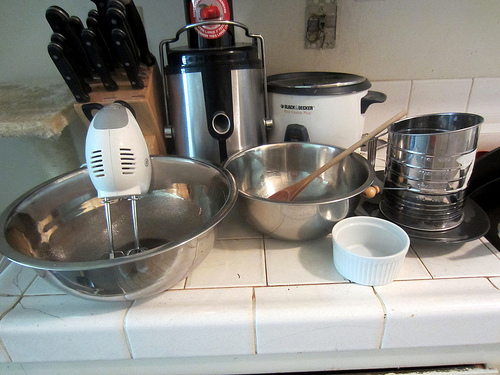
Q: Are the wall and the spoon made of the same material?
A: No, the wall is made of concrete and the spoon is made of wood.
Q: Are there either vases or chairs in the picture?
A: No, there are no chairs or vases.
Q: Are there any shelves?
A: No, there are no shelves.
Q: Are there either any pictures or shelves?
A: No, there are no shelves or pictures.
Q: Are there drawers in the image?
A: No, there are no drawers.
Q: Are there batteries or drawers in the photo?
A: No, there are no drawers or batteries.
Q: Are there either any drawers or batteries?
A: No, there are no drawers or batteries.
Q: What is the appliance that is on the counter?
A: The appliance is a cooker.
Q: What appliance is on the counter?
A: The appliance is a cooker.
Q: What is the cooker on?
A: The cooker is on the counter.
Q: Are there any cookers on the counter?
A: Yes, there is a cooker on the counter.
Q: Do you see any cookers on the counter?
A: Yes, there is a cooker on the counter.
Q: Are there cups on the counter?
A: No, there is a cooker on the counter.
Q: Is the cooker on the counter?
A: Yes, the cooker is on the counter.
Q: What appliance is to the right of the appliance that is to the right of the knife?
A: The appliance is a cooker.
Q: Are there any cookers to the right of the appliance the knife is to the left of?
A: Yes, there is a cooker to the right of the appliance.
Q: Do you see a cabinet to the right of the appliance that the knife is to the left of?
A: No, there is a cooker to the right of the appliance.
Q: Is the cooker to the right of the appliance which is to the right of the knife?
A: Yes, the cooker is to the right of the appliance.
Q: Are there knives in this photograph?
A: Yes, there is a knife.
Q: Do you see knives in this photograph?
A: Yes, there is a knife.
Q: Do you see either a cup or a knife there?
A: Yes, there is a knife.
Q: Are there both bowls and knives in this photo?
A: Yes, there are both a knife and a bowl.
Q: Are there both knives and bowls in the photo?
A: Yes, there are both a knife and a bowl.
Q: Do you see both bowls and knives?
A: Yes, there are both a knife and a bowl.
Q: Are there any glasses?
A: No, there are no glasses.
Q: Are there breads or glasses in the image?
A: No, there are no glasses or breads.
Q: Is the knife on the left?
A: Yes, the knife is on the left of the image.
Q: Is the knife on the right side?
A: No, the knife is on the left of the image.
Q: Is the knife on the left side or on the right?
A: The knife is on the left of the image.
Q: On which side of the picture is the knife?
A: The knife is on the left of the image.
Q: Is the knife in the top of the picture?
A: Yes, the knife is in the top of the image.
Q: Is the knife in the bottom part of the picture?
A: No, the knife is in the top of the image.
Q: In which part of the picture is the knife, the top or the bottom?
A: The knife is in the top of the image.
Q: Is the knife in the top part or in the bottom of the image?
A: The knife is in the top of the image.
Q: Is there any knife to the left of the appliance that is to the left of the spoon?
A: Yes, there is a knife to the left of the appliance.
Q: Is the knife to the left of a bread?
A: No, the knife is to the left of the appliance.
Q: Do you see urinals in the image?
A: No, there are no urinals.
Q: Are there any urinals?
A: No, there are no urinals.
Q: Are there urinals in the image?
A: No, there are no urinals.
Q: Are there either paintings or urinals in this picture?
A: No, there are no urinals or paintings.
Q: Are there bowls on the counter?
A: Yes, there is a bowl on the counter.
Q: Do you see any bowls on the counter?
A: Yes, there is a bowl on the counter.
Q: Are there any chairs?
A: No, there are no chairs.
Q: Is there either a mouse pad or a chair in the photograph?
A: No, there are no chairs or mouse pads.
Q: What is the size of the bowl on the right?
A: The bowl is small.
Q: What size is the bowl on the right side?
A: The bowl is small.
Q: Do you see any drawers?
A: No, there are no drawers.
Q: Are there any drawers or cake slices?
A: No, there are no drawers or cake slices.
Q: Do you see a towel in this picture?
A: No, there are no towels.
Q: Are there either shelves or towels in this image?
A: No, there are no towels or shelves.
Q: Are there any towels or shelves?
A: No, there are no towels or shelves.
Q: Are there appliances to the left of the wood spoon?
A: Yes, there is an appliance to the left of the spoon.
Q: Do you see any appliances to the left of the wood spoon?
A: Yes, there is an appliance to the left of the spoon.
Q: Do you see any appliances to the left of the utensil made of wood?
A: Yes, there is an appliance to the left of the spoon.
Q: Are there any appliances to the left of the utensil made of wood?
A: Yes, there is an appliance to the left of the spoon.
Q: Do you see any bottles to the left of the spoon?
A: No, there is an appliance to the left of the spoon.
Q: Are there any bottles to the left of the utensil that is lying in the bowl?
A: No, there is an appliance to the left of the spoon.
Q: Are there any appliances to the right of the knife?
A: Yes, there is an appliance to the right of the knife.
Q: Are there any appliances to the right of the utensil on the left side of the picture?
A: Yes, there is an appliance to the right of the knife.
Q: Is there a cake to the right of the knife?
A: No, there is an appliance to the right of the knife.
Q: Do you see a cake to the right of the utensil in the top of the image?
A: No, there is an appliance to the right of the knife.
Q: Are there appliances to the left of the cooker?
A: Yes, there is an appliance to the left of the cooker.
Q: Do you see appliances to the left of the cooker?
A: Yes, there is an appliance to the left of the cooker.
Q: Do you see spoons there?
A: Yes, there is a spoon.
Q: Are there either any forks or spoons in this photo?
A: Yes, there is a spoon.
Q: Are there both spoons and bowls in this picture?
A: Yes, there are both a spoon and a bowl.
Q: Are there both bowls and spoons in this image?
A: Yes, there are both a spoon and a bowl.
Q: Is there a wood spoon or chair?
A: Yes, there is a wood spoon.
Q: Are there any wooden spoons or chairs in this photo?
A: Yes, there is a wood spoon.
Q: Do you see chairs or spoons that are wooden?
A: Yes, the spoon is wooden.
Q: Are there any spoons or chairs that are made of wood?
A: Yes, the spoon is made of wood.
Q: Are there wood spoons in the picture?
A: Yes, there is a wood spoon.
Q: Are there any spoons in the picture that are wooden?
A: Yes, there is a spoon that is wooden.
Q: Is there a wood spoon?
A: Yes, there is a spoon that is made of wood.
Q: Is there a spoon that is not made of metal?
A: Yes, there is a spoon that is made of wood.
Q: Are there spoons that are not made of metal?
A: Yes, there is a spoon that is made of wood.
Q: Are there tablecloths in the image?
A: No, there are no tablecloths.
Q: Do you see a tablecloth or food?
A: No, there are no tablecloths or food.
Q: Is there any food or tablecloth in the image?
A: No, there are no tablecloths or food.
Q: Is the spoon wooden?
A: Yes, the spoon is wooden.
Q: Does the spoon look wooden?
A: Yes, the spoon is wooden.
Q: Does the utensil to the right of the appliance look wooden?
A: Yes, the spoon is wooden.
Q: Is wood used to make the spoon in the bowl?
A: Yes, the spoon is made of wood.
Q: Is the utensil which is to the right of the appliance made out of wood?
A: Yes, the spoon is made of wood.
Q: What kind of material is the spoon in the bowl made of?
A: The spoon is made of wood.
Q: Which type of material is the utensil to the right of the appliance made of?
A: The spoon is made of wood.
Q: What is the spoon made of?
A: The spoon is made of wood.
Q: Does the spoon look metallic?
A: No, the spoon is wooden.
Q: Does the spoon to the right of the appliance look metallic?
A: No, the spoon is wooden.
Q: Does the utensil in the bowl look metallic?
A: No, the spoon is wooden.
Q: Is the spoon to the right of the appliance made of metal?
A: No, the spoon is made of wood.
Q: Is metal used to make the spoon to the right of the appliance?
A: No, the spoon is made of wood.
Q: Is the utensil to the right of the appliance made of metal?
A: No, the spoon is made of wood.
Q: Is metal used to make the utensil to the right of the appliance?
A: No, the spoon is made of wood.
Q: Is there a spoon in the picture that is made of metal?
A: No, there is a spoon but it is made of wood.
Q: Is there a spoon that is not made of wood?
A: No, there is a spoon but it is made of wood.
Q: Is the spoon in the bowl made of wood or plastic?
A: The spoon is made of wood.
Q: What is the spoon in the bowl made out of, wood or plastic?
A: The spoon is made of wood.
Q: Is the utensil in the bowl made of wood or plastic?
A: The spoon is made of wood.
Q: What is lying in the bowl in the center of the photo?
A: The spoon is lying in the bowl.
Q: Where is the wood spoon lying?
A: The spoon is lying in the bowl.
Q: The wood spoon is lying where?
A: The spoon is lying in the bowl.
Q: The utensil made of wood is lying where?
A: The spoon is lying in the bowl.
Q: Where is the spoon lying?
A: The spoon is lying in the bowl.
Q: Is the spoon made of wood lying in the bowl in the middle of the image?
A: Yes, the spoon is lying in the bowl.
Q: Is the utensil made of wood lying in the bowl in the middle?
A: Yes, the spoon is lying in the bowl.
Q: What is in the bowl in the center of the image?
A: The spoon is in the bowl.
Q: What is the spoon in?
A: The spoon is in the bowl.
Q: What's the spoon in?
A: The spoon is in the bowl.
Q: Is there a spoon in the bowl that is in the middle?
A: Yes, there is a spoon in the bowl.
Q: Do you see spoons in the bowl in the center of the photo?
A: Yes, there is a spoon in the bowl.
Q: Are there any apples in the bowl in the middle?
A: No, there is a spoon in the bowl.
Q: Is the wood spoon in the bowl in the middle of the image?
A: Yes, the spoon is in the bowl.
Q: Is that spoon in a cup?
A: No, the spoon is in the bowl.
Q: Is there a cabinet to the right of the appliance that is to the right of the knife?
A: No, there is a spoon to the right of the appliance.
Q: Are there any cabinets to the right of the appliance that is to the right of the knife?
A: No, there is a spoon to the right of the appliance.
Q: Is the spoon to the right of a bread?
A: No, the spoon is to the right of the appliance.